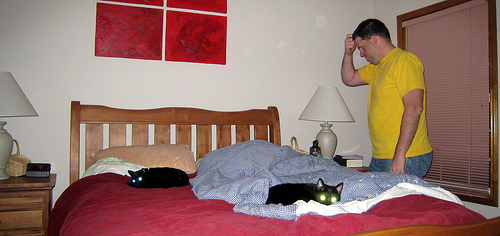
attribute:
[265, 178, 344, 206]
cat — black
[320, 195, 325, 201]
eye — glowing, creepy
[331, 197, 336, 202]
eye — glowing, creepy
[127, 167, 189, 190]
cat — black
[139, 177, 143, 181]
eye — glowing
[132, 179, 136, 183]
eye — glowing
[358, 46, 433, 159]
shirt — yellow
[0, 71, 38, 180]
lamp — white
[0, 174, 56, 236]
table — wooden, brown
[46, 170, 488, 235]
blanket — purple, red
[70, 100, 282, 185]
headboard — brown, wooden, slatted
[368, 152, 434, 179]
jeans — blue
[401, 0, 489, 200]
blinds — down, white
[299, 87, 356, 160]
lamp — white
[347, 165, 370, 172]
table — brown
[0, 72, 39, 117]
shade — white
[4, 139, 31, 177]
basket — small, wicker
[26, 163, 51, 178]
alarm clock — digital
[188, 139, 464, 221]
blanket — blue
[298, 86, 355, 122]
shade — white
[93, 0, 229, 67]
artwork — red, white, abstract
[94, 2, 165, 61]
section — red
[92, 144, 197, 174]
pillow — peach